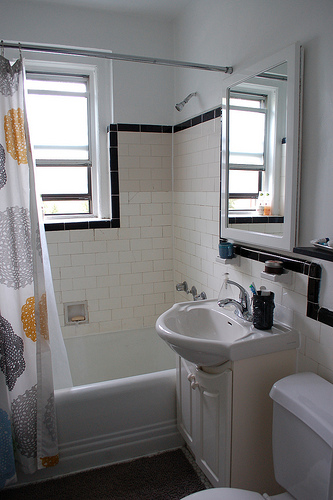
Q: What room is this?
A: Bathroom.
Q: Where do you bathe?
A: Bathtub.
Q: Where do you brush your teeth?
A: Sink.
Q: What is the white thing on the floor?
A: Toilet.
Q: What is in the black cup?
A: Toothbrush.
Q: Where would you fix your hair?
A: Mirror.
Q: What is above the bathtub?
A: Shower head.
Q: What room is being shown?
A: Bathroom.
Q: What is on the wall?
A: Tile.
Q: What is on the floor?
A: Carpet.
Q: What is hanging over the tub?
A: Shower curtain.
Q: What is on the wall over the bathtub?
A: Window.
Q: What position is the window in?
A: Opened.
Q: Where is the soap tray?
A: Wall under the window.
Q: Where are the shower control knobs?
A: Wall beside the sink.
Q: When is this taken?
A: During the daytime.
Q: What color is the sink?
A: White.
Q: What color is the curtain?
A: White, gray, yellow.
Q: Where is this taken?
A: In a bathroom.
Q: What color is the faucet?
A: Silver.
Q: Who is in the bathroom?
A: There is no one present.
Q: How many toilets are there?
A: One.